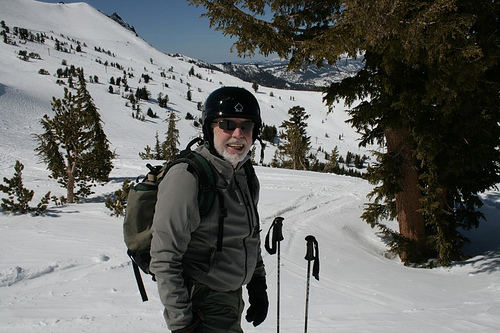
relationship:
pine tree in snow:
[193, 1, 499, 259] [0, 1, 498, 326]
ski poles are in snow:
[266, 216, 319, 332] [0, 1, 498, 326]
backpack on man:
[123, 150, 263, 278] [123, 86, 270, 332]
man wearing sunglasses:
[123, 86, 270, 332] [212, 117, 258, 132]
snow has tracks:
[0, 1, 498, 326] [258, 180, 486, 332]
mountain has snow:
[0, 1, 416, 174] [0, 1, 498, 326]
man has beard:
[123, 86, 270, 332] [213, 137, 253, 164]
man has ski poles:
[123, 86, 270, 332] [266, 216, 319, 332]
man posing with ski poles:
[123, 86, 270, 332] [266, 216, 319, 332]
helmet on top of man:
[201, 86, 263, 152] [123, 86, 270, 332]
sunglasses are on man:
[212, 117, 258, 132] [123, 86, 270, 332]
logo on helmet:
[231, 102, 244, 113] [201, 86, 263, 152]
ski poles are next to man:
[266, 216, 319, 332] [123, 86, 270, 332]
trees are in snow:
[2, 2, 381, 195] [0, 1, 498, 326]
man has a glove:
[123, 86, 270, 332] [246, 297, 268, 325]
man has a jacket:
[123, 86, 270, 332] [147, 139, 262, 329]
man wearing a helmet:
[123, 86, 270, 332] [201, 86, 263, 152]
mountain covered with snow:
[0, 1, 416, 174] [0, 1, 498, 326]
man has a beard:
[123, 86, 270, 332] [213, 137, 255, 163]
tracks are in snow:
[258, 180, 486, 332] [0, 1, 498, 326]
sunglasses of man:
[212, 117, 258, 132] [123, 86, 270, 332]